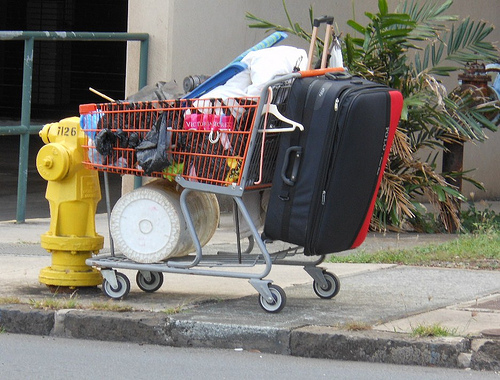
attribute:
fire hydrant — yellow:
[32, 111, 102, 296]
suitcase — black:
[284, 50, 395, 271]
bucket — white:
[107, 179, 203, 268]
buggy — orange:
[72, 75, 398, 346]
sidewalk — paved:
[15, 242, 487, 359]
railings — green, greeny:
[5, 20, 178, 235]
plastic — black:
[113, 114, 222, 171]